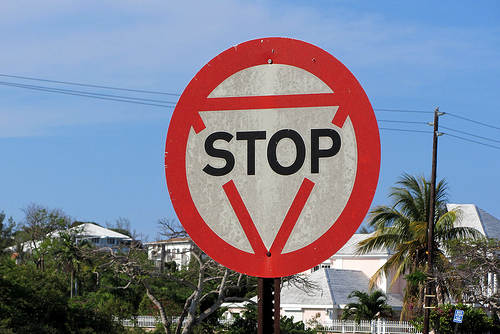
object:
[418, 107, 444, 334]
pole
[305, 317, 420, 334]
fence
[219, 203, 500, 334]
house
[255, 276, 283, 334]
metal post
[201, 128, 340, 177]
stop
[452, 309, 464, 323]
sign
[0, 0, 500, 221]
blue sky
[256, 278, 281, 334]
metal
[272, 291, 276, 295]
dot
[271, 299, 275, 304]
dot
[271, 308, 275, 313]
dot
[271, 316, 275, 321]
dot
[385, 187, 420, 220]
leaf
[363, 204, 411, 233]
leaf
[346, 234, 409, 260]
leaf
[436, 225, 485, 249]
leaf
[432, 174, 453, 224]
leaf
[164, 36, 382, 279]
sign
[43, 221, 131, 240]
roof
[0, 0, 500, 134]
clouds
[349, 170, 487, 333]
palm tree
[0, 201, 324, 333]
trees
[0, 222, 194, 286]
house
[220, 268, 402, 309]
shingle rooftop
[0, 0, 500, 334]
background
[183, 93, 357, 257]
triangle